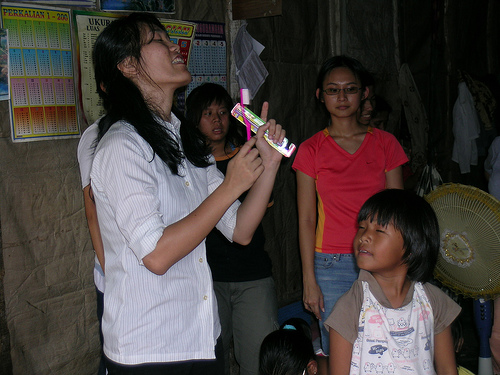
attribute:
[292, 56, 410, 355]
woman — standing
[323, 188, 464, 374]
child — small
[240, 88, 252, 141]
toothbrush — pink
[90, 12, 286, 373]
lady — standing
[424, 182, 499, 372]
fan — yellow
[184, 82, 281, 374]
lady — standing, young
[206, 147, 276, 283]
shirt — orange, black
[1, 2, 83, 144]
calendar — colorful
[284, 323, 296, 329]
hair tie — blue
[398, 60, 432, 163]
coat — hanging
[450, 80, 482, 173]
coat — hanging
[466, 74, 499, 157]
coat — hanging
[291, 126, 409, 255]
shirt — pink, yellow, red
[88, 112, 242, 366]
shirt — striped, white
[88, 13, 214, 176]
hair — black, long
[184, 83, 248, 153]
hair — black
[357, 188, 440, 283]
hair — black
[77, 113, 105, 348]
woman — standing